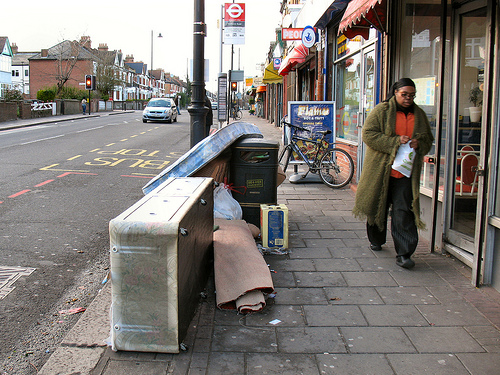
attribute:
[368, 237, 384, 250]
shoe — black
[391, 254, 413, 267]
shoe — black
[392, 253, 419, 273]
shoe — black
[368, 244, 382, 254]
shoe — black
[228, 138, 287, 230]
trash can — green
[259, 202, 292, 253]
trash — pile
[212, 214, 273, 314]
trash — pile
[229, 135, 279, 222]
trash — pile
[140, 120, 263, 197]
trash — pile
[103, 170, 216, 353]
trash — pile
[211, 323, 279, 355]
block — dark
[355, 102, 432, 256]
coat — green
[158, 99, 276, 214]
mattress — old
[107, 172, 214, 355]
box springs — old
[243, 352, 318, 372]
block — dark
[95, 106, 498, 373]
sidewalk — gray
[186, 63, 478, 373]
sidewalk — gray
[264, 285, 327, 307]
block — dark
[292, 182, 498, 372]
sidewalk — grey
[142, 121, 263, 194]
mattress — old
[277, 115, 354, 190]
bicycle — blue, adult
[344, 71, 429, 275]
woman — wearing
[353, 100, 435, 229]
coat — green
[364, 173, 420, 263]
pants — black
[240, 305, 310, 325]
block — dark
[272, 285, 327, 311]
block — dark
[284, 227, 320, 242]
block — dark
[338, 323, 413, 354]
block — dark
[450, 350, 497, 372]
block — dark